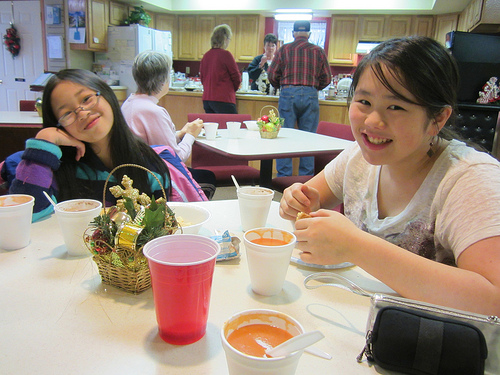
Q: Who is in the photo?
A: Some people.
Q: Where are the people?
A: In kitchen.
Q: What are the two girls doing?
A: Looking at the camera.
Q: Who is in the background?
A: A man.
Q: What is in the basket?
A: Flowers.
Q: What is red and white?
A: The cup.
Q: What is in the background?
A: Cabinets.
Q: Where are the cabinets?
A: Behind the people.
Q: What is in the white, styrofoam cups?
A: Tomato soup.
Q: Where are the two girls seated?
A: Table.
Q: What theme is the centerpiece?
A: Christmas.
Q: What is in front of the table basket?
A: Red cup.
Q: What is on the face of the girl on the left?
A: Glasses.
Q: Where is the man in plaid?
A: Island.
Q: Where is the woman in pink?
A: Seated at another table.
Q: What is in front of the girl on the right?
A: Wallet.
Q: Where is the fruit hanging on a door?
A: Top left corner.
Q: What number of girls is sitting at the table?
A: 2.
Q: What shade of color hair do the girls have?
A: Black.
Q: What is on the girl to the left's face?
A: Glasses.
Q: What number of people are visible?
A: 6.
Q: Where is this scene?
A: A kitchen.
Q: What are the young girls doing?
A: Smiling.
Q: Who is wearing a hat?
A: The man.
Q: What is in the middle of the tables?
A: Baskets.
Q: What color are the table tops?
A: White.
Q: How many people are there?
A: 6.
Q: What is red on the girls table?
A: A cup.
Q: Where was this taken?
A: In a kitchen.